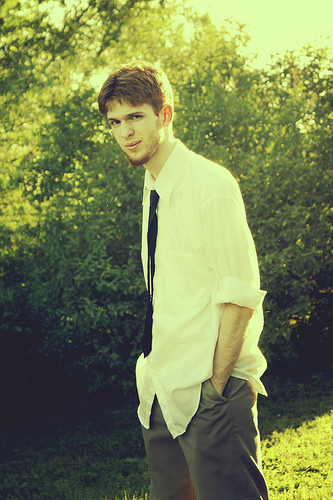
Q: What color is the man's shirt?
A: White.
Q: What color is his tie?
A: Black.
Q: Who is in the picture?
A: 1 man.